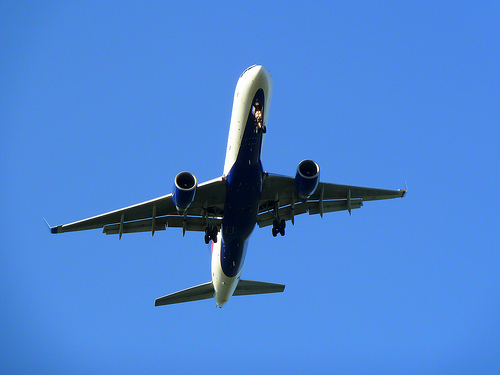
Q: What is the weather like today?
A: It is cloudless.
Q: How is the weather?
A: It is cloudless.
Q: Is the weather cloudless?
A: Yes, it is cloudless.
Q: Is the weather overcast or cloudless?
A: It is cloudless.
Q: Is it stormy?
A: No, it is cloudless.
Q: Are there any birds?
A: No, there are no birds.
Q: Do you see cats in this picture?
A: No, there are no cats.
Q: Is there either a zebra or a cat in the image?
A: No, there are no cats or zebras.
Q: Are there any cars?
A: No, there are no cars.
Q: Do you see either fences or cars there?
A: No, there are no cars or fences.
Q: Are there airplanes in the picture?
A: Yes, there is an airplane.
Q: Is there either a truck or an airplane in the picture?
A: Yes, there is an airplane.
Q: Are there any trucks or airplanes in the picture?
A: Yes, there is an airplane.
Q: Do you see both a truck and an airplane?
A: No, there is an airplane but no trucks.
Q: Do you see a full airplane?
A: Yes, there is a full airplane.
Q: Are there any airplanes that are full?
A: Yes, there is an airplane that is full.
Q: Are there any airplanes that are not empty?
A: Yes, there is an full airplane.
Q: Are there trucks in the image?
A: No, there are no trucks.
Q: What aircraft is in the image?
A: The aircraft is an airplane.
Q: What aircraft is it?
A: The aircraft is an airplane.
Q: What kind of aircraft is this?
A: This is an airplane.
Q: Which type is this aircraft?
A: This is an airplane.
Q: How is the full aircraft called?
A: The aircraft is an airplane.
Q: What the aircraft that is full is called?
A: The aircraft is an airplane.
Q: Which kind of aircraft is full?
A: The aircraft is an airplane.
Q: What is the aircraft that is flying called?
A: The aircraft is an airplane.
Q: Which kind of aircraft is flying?
A: The aircraft is an airplane.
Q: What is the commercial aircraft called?
A: The aircraft is an airplane.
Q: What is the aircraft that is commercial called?
A: The aircraft is an airplane.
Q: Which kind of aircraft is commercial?
A: The aircraft is an airplane.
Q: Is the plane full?
A: Yes, the plane is full.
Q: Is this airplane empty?
A: No, the airplane is full.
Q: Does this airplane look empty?
A: No, the airplane is full.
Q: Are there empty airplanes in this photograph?
A: No, there is an airplane but it is full.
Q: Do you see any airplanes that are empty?
A: No, there is an airplane but it is full.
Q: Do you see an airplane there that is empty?
A: No, there is an airplane but it is full.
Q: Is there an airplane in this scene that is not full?
A: No, there is an airplane but it is full.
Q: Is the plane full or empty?
A: The plane is full.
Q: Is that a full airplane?
A: Yes, that is a full airplane.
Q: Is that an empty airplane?
A: No, that is a full airplane.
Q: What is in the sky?
A: The plane is in the sky.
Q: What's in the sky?
A: The plane is in the sky.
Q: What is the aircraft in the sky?
A: The aircraft is an airplane.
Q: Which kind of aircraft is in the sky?
A: The aircraft is an airplane.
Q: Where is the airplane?
A: The airplane is in the sky.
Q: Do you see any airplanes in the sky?
A: Yes, there is an airplane in the sky.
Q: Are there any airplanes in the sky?
A: Yes, there is an airplane in the sky.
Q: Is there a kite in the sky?
A: No, there is an airplane in the sky.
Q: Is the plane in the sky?
A: Yes, the plane is in the sky.